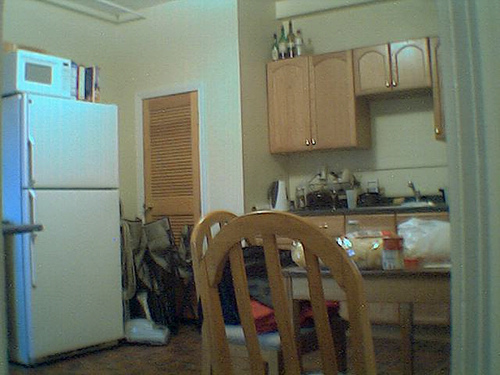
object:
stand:
[397, 297, 417, 374]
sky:
[412, 123, 451, 168]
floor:
[0, 325, 454, 375]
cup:
[346, 188, 358, 209]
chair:
[188, 209, 350, 374]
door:
[141, 89, 202, 235]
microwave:
[4, 47, 72, 99]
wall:
[0, 0, 499, 374]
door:
[20, 92, 120, 188]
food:
[381, 237, 406, 271]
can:
[381, 230, 405, 271]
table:
[273, 266, 453, 374]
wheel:
[264, 15, 309, 68]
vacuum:
[126, 315, 171, 346]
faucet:
[406, 180, 421, 203]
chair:
[197, 210, 382, 374]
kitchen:
[0, 0, 488, 374]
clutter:
[297, 167, 383, 210]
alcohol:
[271, 20, 305, 61]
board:
[291, 194, 449, 215]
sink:
[400, 199, 437, 207]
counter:
[283, 202, 453, 216]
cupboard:
[266, 35, 445, 154]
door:
[264, 54, 314, 156]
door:
[309, 47, 359, 150]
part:
[150, 347, 179, 367]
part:
[398, 297, 415, 374]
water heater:
[145, 90, 202, 245]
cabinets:
[267, 34, 444, 157]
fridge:
[1, 90, 124, 370]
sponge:
[393, 198, 404, 206]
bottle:
[266, 20, 311, 61]